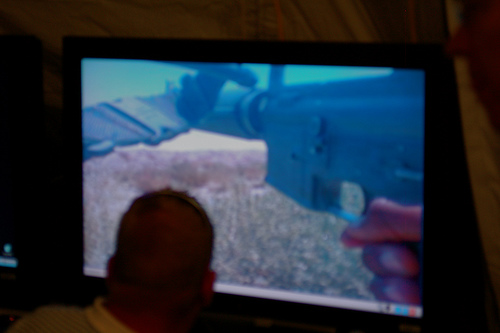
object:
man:
[4, 186, 221, 332]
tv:
[60, 34, 445, 332]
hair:
[102, 189, 218, 323]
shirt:
[4, 295, 133, 332]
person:
[334, 183, 422, 306]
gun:
[229, 70, 431, 222]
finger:
[339, 221, 423, 249]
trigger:
[354, 185, 380, 223]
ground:
[223, 221, 322, 267]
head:
[106, 183, 215, 332]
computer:
[0, 240, 30, 280]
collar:
[79, 291, 135, 333]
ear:
[201, 268, 221, 304]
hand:
[338, 197, 431, 305]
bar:
[84, 266, 423, 316]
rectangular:
[65, 36, 436, 332]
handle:
[330, 179, 425, 316]